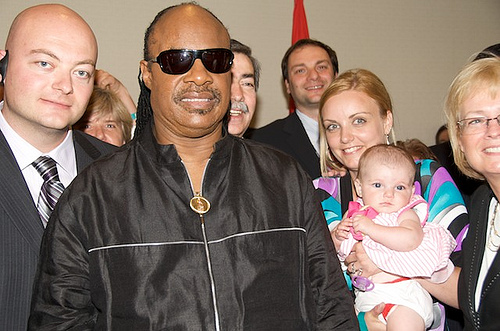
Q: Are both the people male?
A: No, they are both male and female.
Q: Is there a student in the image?
A: No, there are no students.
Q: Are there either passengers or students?
A: No, there are no students or passengers.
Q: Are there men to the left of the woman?
A: Yes, there is a man to the left of the woman.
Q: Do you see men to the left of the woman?
A: Yes, there is a man to the left of the woman.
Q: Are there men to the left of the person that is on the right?
A: Yes, there is a man to the left of the woman.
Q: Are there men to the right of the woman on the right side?
A: No, the man is to the left of the woman.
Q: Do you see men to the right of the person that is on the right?
A: No, the man is to the left of the woman.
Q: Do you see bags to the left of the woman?
A: No, there is a man to the left of the woman.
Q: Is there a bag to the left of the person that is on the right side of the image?
A: No, there is a man to the left of the woman.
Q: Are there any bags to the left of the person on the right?
A: No, there is a man to the left of the woman.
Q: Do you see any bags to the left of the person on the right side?
A: No, there is a man to the left of the woman.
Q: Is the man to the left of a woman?
A: Yes, the man is to the left of a woman.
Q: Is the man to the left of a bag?
A: No, the man is to the left of a woman.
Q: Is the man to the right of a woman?
A: No, the man is to the left of a woman.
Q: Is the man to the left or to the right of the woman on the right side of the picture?
A: The man is to the left of the woman.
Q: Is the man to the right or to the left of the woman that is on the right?
A: The man is to the left of the woman.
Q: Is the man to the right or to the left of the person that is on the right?
A: The man is to the left of the woman.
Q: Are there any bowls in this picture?
A: No, there are no bowls.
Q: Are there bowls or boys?
A: No, there are no bowls or boys.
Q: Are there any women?
A: Yes, there is a woman.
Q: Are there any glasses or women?
A: Yes, there is a woman.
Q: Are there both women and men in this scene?
A: Yes, there are both a woman and a man.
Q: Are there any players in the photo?
A: No, there are no players.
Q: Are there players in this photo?
A: No, there are no players.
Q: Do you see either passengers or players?
A: No, there are no players or passengers.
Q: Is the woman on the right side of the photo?
A: Yes, the woman is on the right of the image.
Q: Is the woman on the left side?
A: No, the woman is on the right of the image.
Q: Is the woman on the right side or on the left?
A: The woman is on the right of the image.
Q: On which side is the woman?
A: The woman is on the right of the image.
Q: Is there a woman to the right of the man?
A: Yes, there is a woman to the right of the man.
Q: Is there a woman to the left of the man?
A: No, the woman is to the right of the man.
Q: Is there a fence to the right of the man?
A: No, there is a woman to the right of the man.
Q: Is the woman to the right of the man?
A: Yes, the woman is to the right of the man.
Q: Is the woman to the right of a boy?
A: No, the woman is to the right of the man.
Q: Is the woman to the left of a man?
A: No, the woman is to the right of a man.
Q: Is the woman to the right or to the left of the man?
A: The woman is to the right of the man.